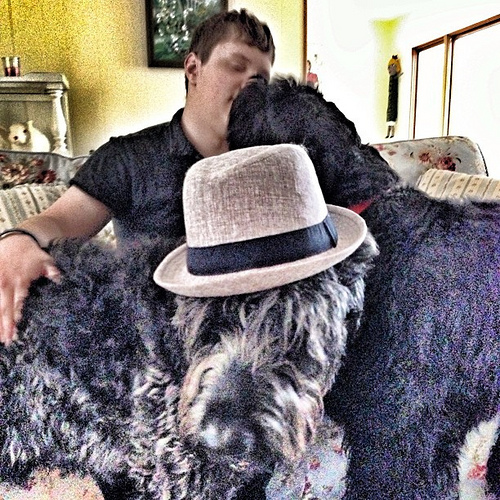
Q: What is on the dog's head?
A: Hat.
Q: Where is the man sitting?
A: Sofa.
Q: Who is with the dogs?
A: Man with a black shirt.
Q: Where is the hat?
A: On the dog.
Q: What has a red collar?
A: The black dog.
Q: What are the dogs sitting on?
A: The man.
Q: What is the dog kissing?
A: The man.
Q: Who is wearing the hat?
A: Gray dog.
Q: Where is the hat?
A: On gray dog.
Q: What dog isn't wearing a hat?
A: Black dog.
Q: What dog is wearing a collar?
A: Black dog.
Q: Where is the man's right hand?
A: On gray dog.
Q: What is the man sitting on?
A: Couch.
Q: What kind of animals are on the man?
A: Dogs.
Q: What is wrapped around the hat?
A: Ribbon.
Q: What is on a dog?
A: A hat.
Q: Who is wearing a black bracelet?
A: A man.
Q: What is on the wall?
A: A picture.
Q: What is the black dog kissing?
A: A man.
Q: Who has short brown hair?
A: A man.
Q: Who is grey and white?
A: A dog.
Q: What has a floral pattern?
A: A couch.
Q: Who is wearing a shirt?
A: A man.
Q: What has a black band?
A: A hat.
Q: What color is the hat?
A: Brown.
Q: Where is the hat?
A: On the dog's head.